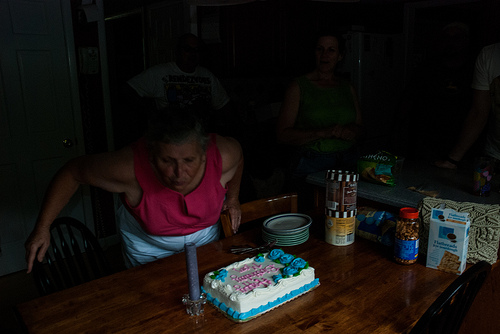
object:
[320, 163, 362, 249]
ice cream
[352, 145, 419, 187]
chips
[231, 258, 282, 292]
pink letters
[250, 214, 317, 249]
plates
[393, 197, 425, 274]
jar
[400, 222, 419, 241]
nuts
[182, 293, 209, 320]
glass holder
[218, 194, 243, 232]
left hand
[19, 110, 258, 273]
old woman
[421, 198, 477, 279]
box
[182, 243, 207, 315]
candle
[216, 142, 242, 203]
arm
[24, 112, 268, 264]
woman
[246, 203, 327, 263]
plates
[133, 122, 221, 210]
woman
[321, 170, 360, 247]
two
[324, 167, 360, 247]
cartons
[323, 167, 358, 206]
ice cream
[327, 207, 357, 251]
ice cream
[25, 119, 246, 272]
old woman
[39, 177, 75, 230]
arm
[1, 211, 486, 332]
table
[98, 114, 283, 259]
person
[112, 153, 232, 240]
shirt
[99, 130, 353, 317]
woman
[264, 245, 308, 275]
flowers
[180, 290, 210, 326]
holder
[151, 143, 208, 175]
eyes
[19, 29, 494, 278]
people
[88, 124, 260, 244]
woman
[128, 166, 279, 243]
top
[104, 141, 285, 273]
woman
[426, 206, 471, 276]
box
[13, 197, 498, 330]
table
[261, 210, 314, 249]
plates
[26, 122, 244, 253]
woman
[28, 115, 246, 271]
woman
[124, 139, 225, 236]
shirt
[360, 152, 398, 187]
bag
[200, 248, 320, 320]
cake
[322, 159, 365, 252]
icecream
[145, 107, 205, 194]
head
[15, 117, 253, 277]
woman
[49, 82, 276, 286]
woman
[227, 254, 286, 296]
writing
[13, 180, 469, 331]
table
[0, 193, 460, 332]
table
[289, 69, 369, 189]
top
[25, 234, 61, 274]
hand